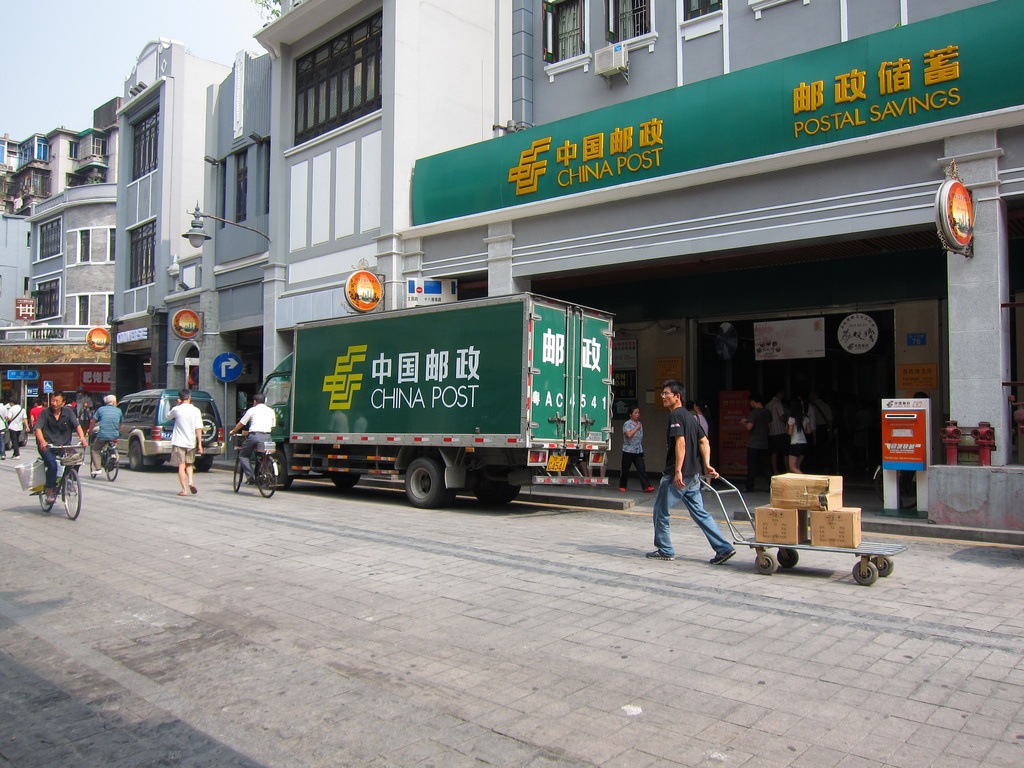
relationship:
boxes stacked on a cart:
[744, 467, 866, 547] [686, 463, 905, 589]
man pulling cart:
[647, 372, 736, 571] [686, 463, 905, 589]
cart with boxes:
[686, 463, 905, 589] [744, 467, 866, 547]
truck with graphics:
[247, 290, 623, 511] [312, 322, 492, 429]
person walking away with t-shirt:
[155, 381, 212, 503] [161, 402, 205, 450]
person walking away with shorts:
[155, 381, 212, 503] [159, 443, 201, 469]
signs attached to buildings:
[0, 175, 983, 361] [6, 7, 987, 522]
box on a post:
[878, 390, 939, 477] [893, 474, 926, 518]